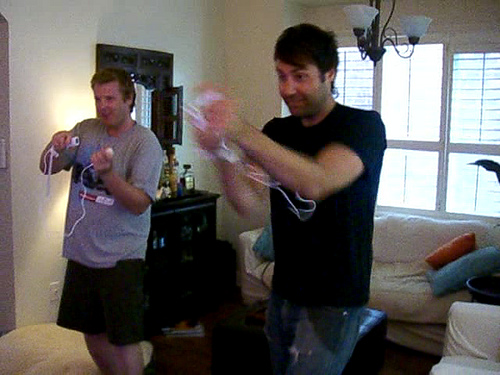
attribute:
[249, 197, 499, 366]
couch — white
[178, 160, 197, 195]
bottle — glass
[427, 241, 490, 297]
cushions — blue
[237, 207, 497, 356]
sofa — white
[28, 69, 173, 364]
man — playing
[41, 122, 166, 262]
shirt — grey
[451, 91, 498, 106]
window blind — white, plastic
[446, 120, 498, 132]
blind — white, plastic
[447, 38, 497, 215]
window — covered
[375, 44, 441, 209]
window — covered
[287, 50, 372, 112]
window — covered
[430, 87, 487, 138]
window blind — white, plastic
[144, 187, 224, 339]
chest — black, behind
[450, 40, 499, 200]
window blind — plastic, white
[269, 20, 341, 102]
hair — black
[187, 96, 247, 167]
remote — wii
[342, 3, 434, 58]
light — hanging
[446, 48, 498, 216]
blind — white, plastic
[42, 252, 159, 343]
shorts — black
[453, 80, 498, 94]
blind — white, plastic, window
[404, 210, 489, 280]
pillows — orange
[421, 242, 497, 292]
pillows — blue